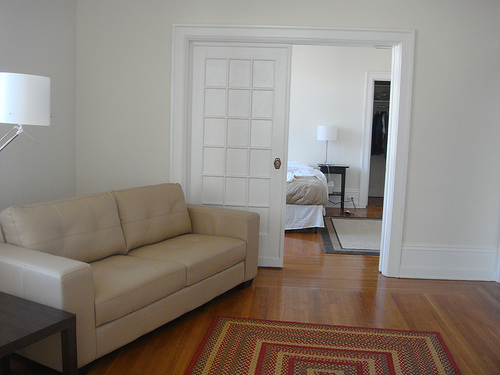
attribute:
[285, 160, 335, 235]
bed — unmade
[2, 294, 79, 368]
end table — brown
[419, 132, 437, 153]
ground — medium brown, hard wood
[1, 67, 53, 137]
lamp shade — creamy, white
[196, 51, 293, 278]
door — Double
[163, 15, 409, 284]
entryway — bedroom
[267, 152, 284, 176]
golden handle — gold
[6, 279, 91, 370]
table — wood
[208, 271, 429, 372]
floor — Polished, hardwood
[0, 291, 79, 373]
table — brown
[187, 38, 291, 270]
door — white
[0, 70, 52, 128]
lamp — white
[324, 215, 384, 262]
rug — tan, brown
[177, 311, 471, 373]
rug — red, brown, beige, area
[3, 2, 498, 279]
wall — white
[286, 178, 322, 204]
comforter — beige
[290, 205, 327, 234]
sheets — white